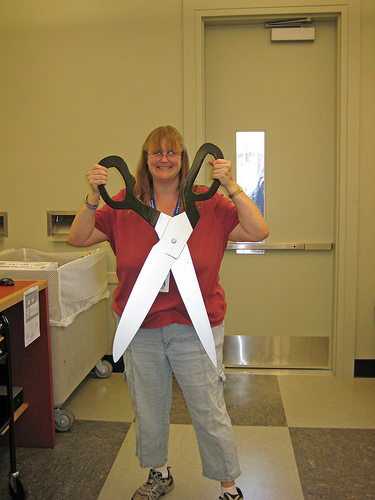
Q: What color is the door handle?
A: Silver.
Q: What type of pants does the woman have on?
A: Capris.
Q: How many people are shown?
A: 1.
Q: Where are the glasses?
A: Woman's face.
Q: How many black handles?
A: 2.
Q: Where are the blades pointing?
A: Down.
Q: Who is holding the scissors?
A: Woman in red.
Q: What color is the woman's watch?
A: Gold.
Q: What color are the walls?
A: White.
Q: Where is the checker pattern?
A: Floor.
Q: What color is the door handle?
A: Silver.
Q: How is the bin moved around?
A: Wheels.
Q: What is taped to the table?
A: Paper.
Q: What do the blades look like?
A: Metal.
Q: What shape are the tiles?
A: Square.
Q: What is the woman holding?
A: Scissors.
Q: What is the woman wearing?
A: Glasses.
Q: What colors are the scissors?
A: Black and Silver.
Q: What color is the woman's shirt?
A: Red.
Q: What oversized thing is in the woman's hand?
A: Scissors.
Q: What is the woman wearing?
A: Khaki jeans.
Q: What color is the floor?
A: Checkerboard pattern.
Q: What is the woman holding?
A: Big scissors.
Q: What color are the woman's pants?
A: Gray.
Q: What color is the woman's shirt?
A: Red.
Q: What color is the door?
A: White.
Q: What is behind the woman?
A: A bin with wheels.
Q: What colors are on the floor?
A: Black and white.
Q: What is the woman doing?
A: Holding big scissors.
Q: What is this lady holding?
A: Scissors.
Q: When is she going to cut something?
A: Soon.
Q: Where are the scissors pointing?
A: Down.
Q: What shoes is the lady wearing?
A: Sneakers.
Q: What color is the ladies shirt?
A: Red.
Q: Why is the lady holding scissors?
A: To cut something.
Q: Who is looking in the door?
A: A man.